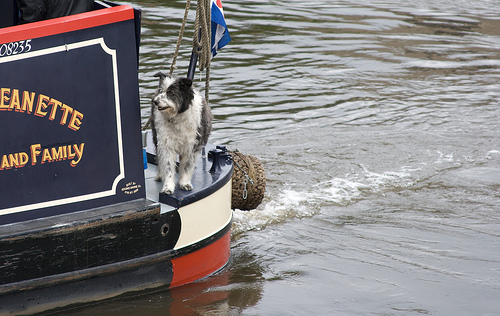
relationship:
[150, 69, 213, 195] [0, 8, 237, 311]
dog standing on boat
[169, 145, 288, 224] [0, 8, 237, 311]
basket at end of boat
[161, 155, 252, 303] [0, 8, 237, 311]
front of boat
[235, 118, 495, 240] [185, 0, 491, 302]
ripples in water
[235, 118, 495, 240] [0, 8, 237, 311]
ripples from boat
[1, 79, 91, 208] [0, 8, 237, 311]
yellow writing on boat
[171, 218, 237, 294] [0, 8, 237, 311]
bottom of boat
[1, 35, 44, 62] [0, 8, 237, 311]
white numbers on boat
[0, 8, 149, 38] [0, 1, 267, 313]
red trim on boat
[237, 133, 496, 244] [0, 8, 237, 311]
bubbley wake of boat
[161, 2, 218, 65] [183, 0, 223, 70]
brown ropes hanging from flag area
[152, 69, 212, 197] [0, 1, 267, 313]
dog on boat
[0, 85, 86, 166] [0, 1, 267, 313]
words on boat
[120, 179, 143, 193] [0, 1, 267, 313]
logo on boat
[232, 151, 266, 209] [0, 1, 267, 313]
tire on boat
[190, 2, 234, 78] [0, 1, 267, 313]
flag on boat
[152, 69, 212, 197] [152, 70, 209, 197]
dog on boat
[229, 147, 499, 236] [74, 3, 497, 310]
wave on water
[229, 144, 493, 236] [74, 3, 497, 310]
wave on water